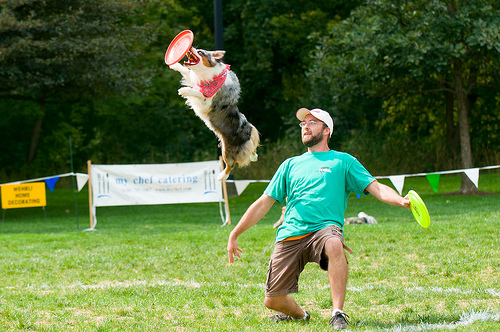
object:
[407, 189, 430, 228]
disk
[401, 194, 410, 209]
hand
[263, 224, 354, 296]
shorts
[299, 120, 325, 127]
glasses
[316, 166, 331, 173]
design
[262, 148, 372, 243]
shirt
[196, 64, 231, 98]
fabric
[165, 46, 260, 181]
dog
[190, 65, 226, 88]
neck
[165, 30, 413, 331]
contestants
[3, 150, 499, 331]
field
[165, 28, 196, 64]
frisbee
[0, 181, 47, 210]
sign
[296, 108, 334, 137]
cap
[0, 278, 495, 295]
boundary lines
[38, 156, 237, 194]
boundaries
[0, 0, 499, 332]
air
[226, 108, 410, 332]
man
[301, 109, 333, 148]
head